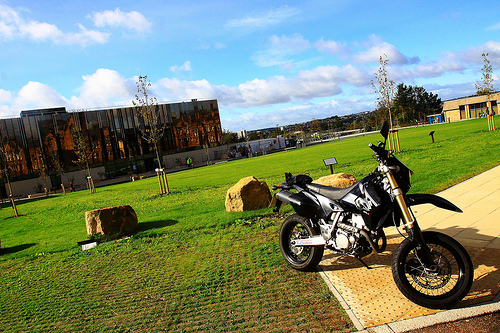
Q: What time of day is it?
A: Daytime.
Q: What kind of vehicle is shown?
A: Motorcycle.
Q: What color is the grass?
A: Green.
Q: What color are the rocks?
A: Brown.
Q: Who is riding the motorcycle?
A: No one.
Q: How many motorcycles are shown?
A: One.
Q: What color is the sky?
A: Blue.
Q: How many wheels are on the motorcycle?
A: Two.